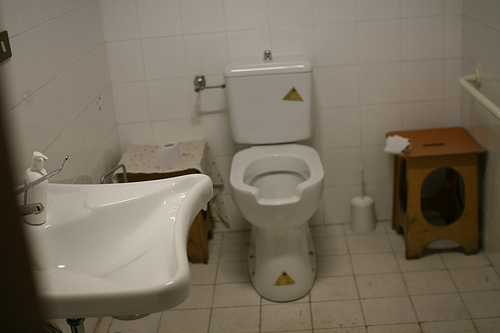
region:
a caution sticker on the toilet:
[263, 259, 307, 299]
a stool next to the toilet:
[363, 66, 497, 285]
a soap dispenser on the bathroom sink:
[26, 139, 74, 244]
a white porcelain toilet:
[186, 37, 353, 307]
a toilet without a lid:
[204, 100, 358, 305]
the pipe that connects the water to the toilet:
[168, 39, 250, 108]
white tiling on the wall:
[105, 5, 198, 104]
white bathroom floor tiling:
[336, 256, 456, 326]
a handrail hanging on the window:
[445, 47, 498, 122]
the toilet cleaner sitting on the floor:
[331, 139, 383, 260]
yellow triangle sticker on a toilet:
[270, 268, 301, 294]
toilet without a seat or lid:
[219, 61, 345, 309]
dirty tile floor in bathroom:
[336, 257, 397, 331]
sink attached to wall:
[33, 152, 225, 329]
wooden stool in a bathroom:
[386, 117, 476, 259]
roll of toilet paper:
[192, 76, 228, 120]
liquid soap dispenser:
[18, 145, 55, 234]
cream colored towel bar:
[450, 61, 492, 127]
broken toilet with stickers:
[208, 56, 338, 313]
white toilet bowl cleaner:
[340, 157, 380, 244]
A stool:
[381, 127, 483, 298]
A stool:
[397, 138, 449, 252]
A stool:
[402, 78, 472, 242]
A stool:
[401, 187, 461, 299]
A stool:
[427, 137, 474, 278]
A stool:
[452, 98, 494, 179]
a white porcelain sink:
[7, 156, 220, 317]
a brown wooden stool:
[382, 119, 487, 264]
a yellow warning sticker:
[269, 267, 296, 292]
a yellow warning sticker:
[278, 82, 302, 107]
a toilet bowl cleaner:
[345, 159, 377, 237]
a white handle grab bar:
[451, 61, 498, 131]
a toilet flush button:
[257, 44, 274, 62]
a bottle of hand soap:
[17, 147, 52, 229]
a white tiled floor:
[115, 219, 495, 326]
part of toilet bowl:
[240, 146, 324, 199]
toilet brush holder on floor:
[350, 143, 375, 233]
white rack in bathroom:
[460, 73, 498, 123]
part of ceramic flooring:
[369, 290, 446, 321]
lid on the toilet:
[222, 59, 306, 74]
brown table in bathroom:
[389, 120, 487, 260]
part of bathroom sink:
[73, 180, 170, 301]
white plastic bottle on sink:
[28, 140, 53, 220]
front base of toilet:
[266, 230, 308, 297]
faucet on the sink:
[15, 205, 55, 222]